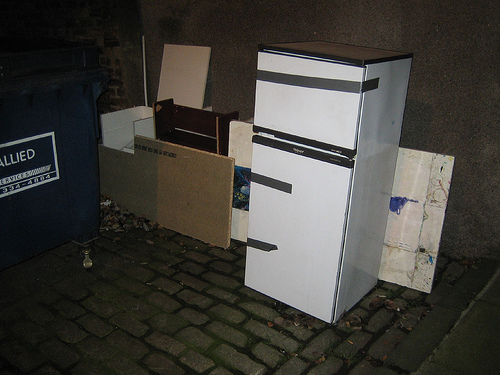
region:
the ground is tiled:
[72, 258, 262, 369]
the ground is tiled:
[95, 254, 277, 368]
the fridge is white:
[230, 36, 392, 342]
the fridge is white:
[228, 58, 373, 345]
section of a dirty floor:
[44, 244, 154, 309]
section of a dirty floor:
[51, 272, 188, 372]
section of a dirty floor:
[285, 325, 405, 372]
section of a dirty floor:
[392, 299, 469, 354]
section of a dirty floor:
[20, 284, 172, 372]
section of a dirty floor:
[92, 240, 260, 340]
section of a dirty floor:
[59, 268, 194, 358]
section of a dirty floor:
[91, 253, 263, 370]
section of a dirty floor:
[27, 275, 139, 360]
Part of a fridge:
[233, 196, 395, 276]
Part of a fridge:
[246, 160, 397, 244]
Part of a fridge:
[235, 126, 400, 229]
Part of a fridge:
[247, 110, 406, 212]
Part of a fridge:
[251, 31, 433, 152]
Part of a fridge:
[234, 224, 410, 333]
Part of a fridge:
[226, 157, 403, 268]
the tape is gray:
[240, 65, 386, 99]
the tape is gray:
[243, 62, 410, 119]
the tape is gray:
[240, 60, 377, 111]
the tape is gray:
[246, 56, 394, 111]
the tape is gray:
[240, 65, 399, 118]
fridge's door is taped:
[213, 40, 350, 343]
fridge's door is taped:
[209, 19, 351, 307]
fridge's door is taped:
[208, 28, 382, 362]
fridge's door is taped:
[213, 38, 359, 342]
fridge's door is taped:
[226, 37, 393, 364]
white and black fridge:
[233, 31, 410, 325]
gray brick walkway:
[20, 214, 466, 373]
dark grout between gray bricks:
[31, 227, 451, 373]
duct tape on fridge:
[229, 63, 386, 262]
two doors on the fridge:
[233, 54, 363, 319]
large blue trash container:
[0, 48, 97, 260]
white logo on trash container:
[1, 127, 66, 207]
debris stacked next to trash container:
[103, 39, 447, 314]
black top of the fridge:
[272, 32, 419, 66]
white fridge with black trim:
[242, 41, 412, 326]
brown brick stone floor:
[0, 227, 498, 374]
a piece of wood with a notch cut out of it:
[97, 134, 234, 249]